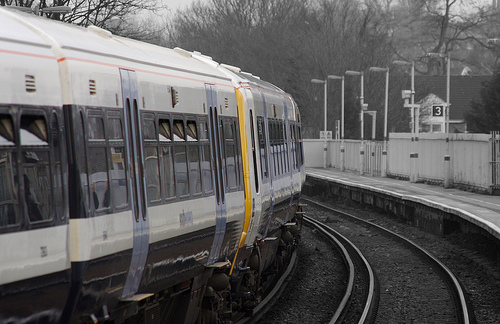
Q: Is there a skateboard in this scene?
A: No, there are no skateboards.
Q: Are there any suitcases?
A: No, there are no suitcases.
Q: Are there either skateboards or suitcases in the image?
A: No, there are no suitcases or skateboards.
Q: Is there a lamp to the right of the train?
A: Yes, there are lamps to the right of the train.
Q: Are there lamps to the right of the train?
A: Yes, there are lamps to the right of the train.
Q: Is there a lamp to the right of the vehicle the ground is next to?
A: Yes, there are lamps to the right of the train.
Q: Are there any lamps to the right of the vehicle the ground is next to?
A: Yes, there are lamps to the right of the train.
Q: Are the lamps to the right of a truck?
A: No, the lamps are to the right of the train.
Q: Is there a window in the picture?
A: Yes, there is a window.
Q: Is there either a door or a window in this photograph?
A: Yes, there is a window.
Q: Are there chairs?
A: No, there are no chairs.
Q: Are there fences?
A: Yes, there is a fence.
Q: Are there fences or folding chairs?
A: Yes, there is a fence.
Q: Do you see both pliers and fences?
A: No, there is a fence but no pliers.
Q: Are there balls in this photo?
A: No, there are no balls.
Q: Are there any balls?
A: No, there are no balls.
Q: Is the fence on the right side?
A: Yes, the fence is on the right of the image.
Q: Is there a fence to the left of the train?
A: No, the fence is to the right of the train.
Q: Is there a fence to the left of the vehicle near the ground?
A: No, the fence is to the right of the train.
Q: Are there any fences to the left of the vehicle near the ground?
A: No, the fence is to the right of the train.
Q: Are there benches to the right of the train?
A: No, there is a fence to the right of the train.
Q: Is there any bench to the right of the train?
A: No, there is a fence to the right of the train.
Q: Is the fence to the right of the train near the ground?
A: Yes, the fence is to the right of the train.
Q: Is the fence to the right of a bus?
A: No, the fence is to the right of the train.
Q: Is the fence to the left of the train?
A: No, the fence is to the right of the train.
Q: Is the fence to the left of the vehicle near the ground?
A: No, the fence is to the right of the train.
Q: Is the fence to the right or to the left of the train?
A: The fence is to the right of the train.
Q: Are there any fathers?
A: No, there are no fathers.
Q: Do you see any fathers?
A: No, there are no fathers.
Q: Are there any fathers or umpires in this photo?
A: No, there are no fathers or umpires.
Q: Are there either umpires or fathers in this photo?
A: No, there are no fathers or umpires.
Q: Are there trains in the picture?
A: Yes, there is a train.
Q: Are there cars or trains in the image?
A: Yes, there is a train.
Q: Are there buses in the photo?
A: No, there are no buses.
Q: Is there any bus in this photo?
A: No, there are no buses.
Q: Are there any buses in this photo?
A: No, there are no buses.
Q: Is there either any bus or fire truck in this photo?
A: No, there are no buses or fire trucks.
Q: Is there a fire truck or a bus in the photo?
A: No, there are no buses or fire trucks.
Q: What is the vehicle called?
A: The vehicle is a train.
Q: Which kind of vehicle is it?
A: The vehicle is a train.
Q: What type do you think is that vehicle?
A: That is a train.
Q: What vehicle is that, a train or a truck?
A: That is a train.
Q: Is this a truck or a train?
A: This is a train.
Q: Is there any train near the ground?
A: Yes, there is a train near the ground.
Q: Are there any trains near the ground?
A: Yes, there is a train near the ground.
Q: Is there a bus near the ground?
A: No, there is a train near the ground.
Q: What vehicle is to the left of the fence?
A: The vehicle is a train.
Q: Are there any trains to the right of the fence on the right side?
A: No, the train is to the left of the fence.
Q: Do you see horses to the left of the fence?
A: No, there is a train to the left of the fence.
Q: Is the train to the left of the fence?
A: Yes, the train is to the left of the fence.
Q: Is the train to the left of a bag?
A: No, the train is to the left of the fence.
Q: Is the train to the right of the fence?
A: No, the train is to the left of the fence.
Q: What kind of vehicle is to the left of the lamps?
A: The vehicle is a train.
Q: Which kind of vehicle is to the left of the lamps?
A: The vehicle is a train.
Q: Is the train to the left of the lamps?
A: Yes, the train is to the left of the lamps.